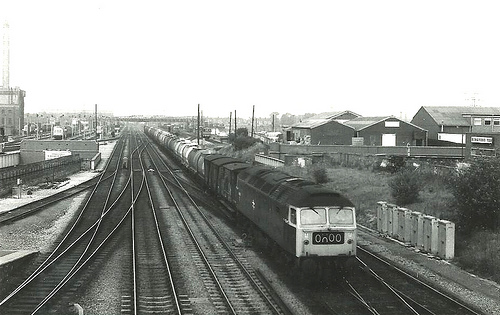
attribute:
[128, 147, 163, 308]
track — empty, wood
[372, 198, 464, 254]
boxes — electrical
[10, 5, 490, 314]
picture — black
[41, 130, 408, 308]
tracks — split, grey, railroad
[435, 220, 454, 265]
object — rectangular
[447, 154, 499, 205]
bush — large, small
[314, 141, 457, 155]
fence — long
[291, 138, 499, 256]
ground — grassy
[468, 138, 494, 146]
sign — white